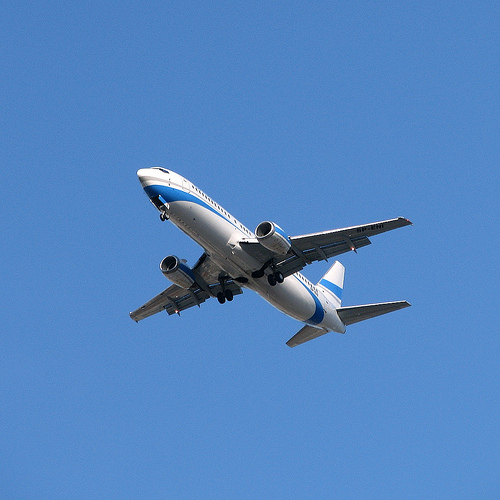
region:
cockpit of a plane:
[123, 154, 186, 222]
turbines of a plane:
[136, 248, 210, 293]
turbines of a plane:
[254, 213, 311, 273]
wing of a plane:
[287, 150, 439, 290]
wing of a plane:
[115, 280, 180, 347]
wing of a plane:
[345, 295, 428, 338]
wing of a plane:
[275, 320, 321, 352]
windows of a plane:
[185, 173, 249, 224]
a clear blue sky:
[82, 383, 332, 486]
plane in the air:
[57, 139, 429, 356]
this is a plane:
[74, 110, 429, 410]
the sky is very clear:
[199, 396, 251, 455]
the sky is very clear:
[277, 393, 379, 478]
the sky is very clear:
[83, 362, 209, 457]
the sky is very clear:
[236, 370, 306, 432]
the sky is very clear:
[391, 229, 493, 344]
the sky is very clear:
[131, 361, 259, 466]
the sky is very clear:
[321, 52, 420, 154]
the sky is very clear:
[83, 15, 203, 110]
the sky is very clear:
[207, 54, 328, 159]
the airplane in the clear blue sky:
[128, 164, 410, 349]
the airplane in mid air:
[129, 163, 414, 346]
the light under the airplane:
[350, 245, 355, 251]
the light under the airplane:
[173, 309, 178, 313]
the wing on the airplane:
[240, 215, 412, 265]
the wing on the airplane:
[127, 250, 228, 322]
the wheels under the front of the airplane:
[160, 210, 170, 220]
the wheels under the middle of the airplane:
[214, 269, 284, 303]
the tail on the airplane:
[317, 260, 344, 310]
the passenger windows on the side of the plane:
[190, 184, 319, 293]